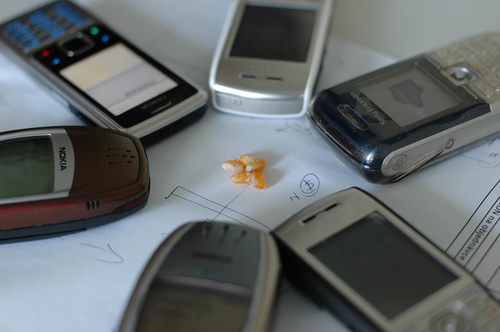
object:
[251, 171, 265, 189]
kernel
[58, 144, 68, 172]
nokia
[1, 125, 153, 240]
phone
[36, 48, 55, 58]
button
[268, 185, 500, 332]
phone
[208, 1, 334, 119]
mobile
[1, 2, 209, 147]
phone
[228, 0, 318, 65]
screen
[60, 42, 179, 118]
screen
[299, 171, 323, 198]
sign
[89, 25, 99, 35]
button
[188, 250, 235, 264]
letters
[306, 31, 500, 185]
phone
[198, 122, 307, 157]
paper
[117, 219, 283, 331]
phone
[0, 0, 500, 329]
phones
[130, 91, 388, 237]
circle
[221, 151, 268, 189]
kernels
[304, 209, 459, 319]
screen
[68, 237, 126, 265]
arrow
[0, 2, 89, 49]
buttons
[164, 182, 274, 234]
lines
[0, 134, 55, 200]
screen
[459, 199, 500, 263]
words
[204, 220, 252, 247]
holes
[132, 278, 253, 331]
screen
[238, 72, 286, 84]
earpiece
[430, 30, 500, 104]
keypad